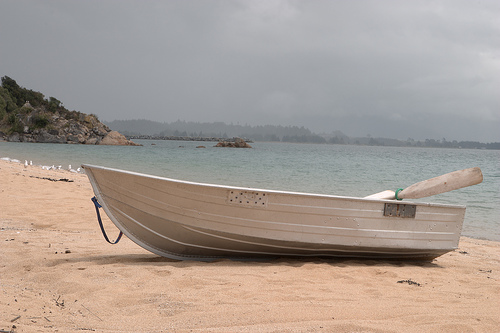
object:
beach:
[0, 159, 500, 332]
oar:
[360, 168, 483, 200]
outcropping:
[212, 136, 254, 149]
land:
[0, 69, 144, 147]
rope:
[91, 193, 124, 245]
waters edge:
[81, 162, 465, 211]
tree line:
[99, 117, 328, 144]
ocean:
[0, 138, 500, 240]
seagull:
[23, 159, 28, 168]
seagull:
[68, 164, 71, 170]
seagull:
[29, 160, 34, 167]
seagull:
[76, 167, 81, 172]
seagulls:
[40, 165, 45, 170]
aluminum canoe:
[76, 157, 487, 265]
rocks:
[0, 73, 150, 147]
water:
[0, 133, 500, 246]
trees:
[49, 95, 62, 108]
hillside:
[0, 71, 137, 144]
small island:
[213, 136, 253, 148]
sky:
[0, 0, 500, 144]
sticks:
[6, 314, 23, 325]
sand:
[0, 154, 500, 333]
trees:
[367, 137, 385, 146]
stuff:
[64, 248, 73, 254]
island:
[99, 118, 499, 151]